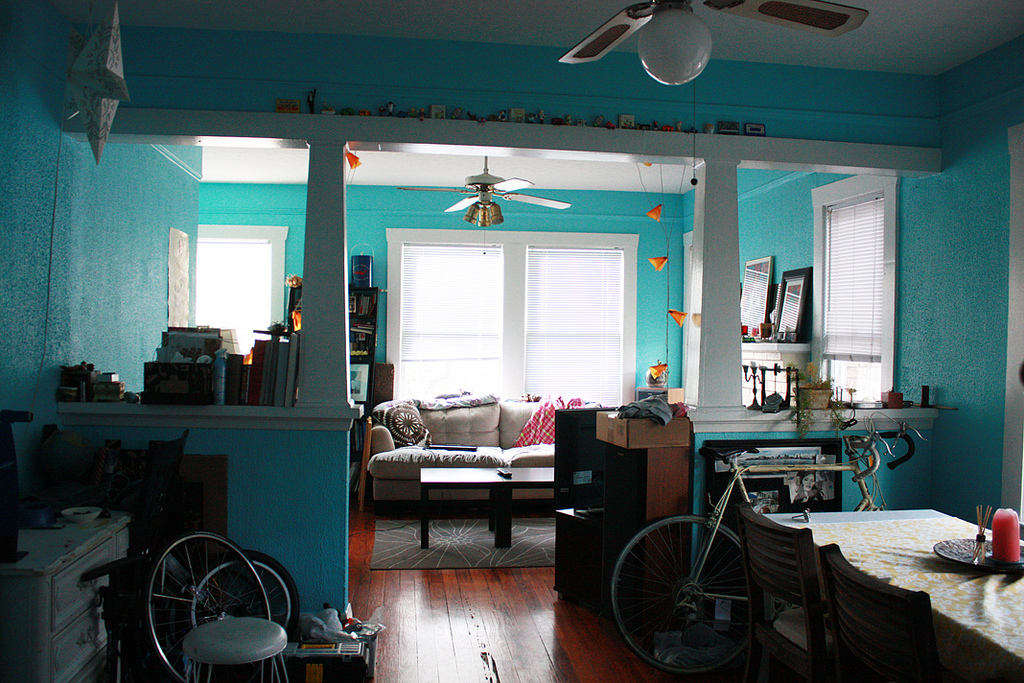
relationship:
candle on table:
[973, 497, 1021, 564] [798, 510, 954, 625]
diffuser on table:
[954, 504, 991, 569] [856, 528, 921, 589]